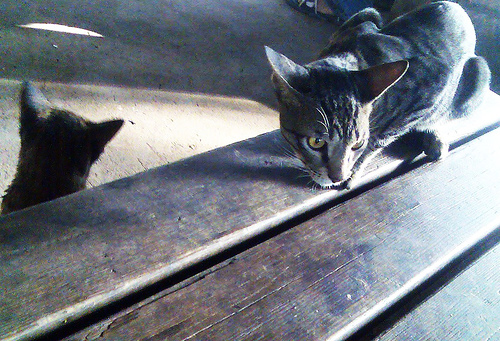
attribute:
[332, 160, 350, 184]
nose — small, pinky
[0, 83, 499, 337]
wood slates — wooden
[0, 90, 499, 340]
bench — brown, wooden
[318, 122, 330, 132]
hair — long, white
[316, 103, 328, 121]
hair — white, long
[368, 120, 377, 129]
hair — white, long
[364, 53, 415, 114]
ear — furry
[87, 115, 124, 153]
ear — small, furry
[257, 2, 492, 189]
cat — crouched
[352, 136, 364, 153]
eye — little, white, yellow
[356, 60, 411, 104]
ear — slanted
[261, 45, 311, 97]
ear — slanted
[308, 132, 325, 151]
eye — yellow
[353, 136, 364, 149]
eye — yellow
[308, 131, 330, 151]
eye — yellow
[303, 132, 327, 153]
eye — bright green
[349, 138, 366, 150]
eye — bright green